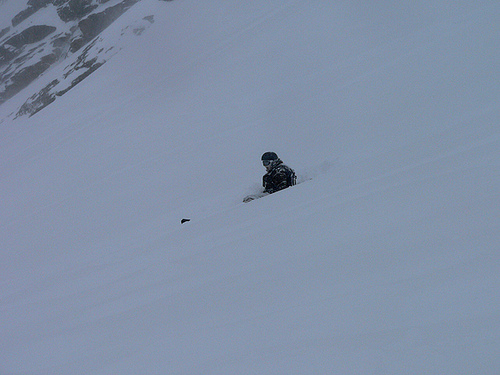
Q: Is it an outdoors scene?
A: Yes, it is outdoors.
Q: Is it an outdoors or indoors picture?
A: It is outdoors.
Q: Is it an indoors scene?
A: No, it is outdoors.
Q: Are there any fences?
A: No, there are no fences.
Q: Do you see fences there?
A: No, there are no fences.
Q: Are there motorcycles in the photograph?
A: No, there are no motorcycles.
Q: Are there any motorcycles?
A: No, there are no motorcycles.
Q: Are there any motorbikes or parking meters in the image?
A: No, there are no motorbikes or parking meters.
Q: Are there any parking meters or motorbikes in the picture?
A: No, there are no motorbikes or parking meters.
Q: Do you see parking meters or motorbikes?
A: No, there are no motorbikes or parking meters.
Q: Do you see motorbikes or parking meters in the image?
A: No, there are no motorbikes or parking meters.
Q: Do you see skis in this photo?
A: No, there are no skis.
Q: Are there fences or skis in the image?
A: No, there are no skis or fences.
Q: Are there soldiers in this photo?
A: No, there are no soldiers.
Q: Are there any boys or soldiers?
A: No, there are no soldiers or boys.